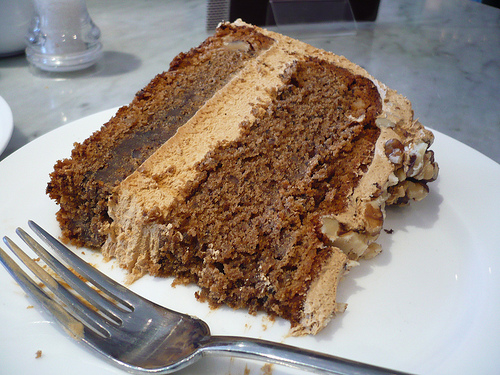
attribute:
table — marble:
[0, 0, 500, 161]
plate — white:
[2, 144, 487, 374]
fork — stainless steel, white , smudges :
[0, 218, 394, 373]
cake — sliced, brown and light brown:
[48, 9, 447, 349]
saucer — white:
[3, 100, 499, 373]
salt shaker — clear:
[25, 0, 107, 75]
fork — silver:
[1, 224, 218, 372]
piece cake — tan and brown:
[110, 26, 416, 271]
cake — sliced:
[112, 81, 467, 266]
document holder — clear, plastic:
[267, 6, 387, 42]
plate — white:
[0, 103, 497, 373]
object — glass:
[19, 2, 103, 73]